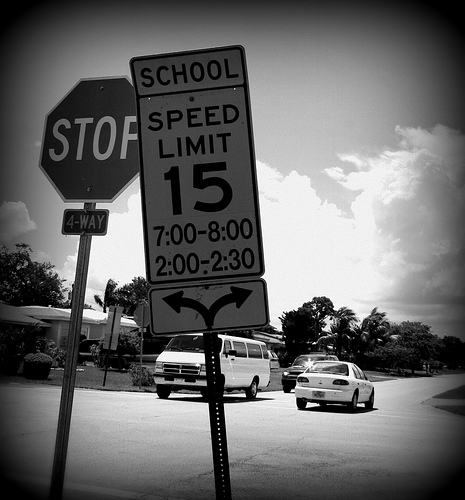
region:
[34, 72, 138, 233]
4-way stop sign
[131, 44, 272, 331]
school zone speed limit sign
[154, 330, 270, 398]
white van in intersectino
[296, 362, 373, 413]
white car in the intersection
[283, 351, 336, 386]
truck behind the white van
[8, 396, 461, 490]
intersection of two roads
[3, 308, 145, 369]
house on the corner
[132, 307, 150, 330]
stop sign on far corner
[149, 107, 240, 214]
speed limit in black lettering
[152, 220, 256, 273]
times under the 15 MPH speed limit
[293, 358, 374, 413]
A small white car.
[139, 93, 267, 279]
A speed limit sign.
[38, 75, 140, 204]
A stop sign.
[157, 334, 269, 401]
A large white van.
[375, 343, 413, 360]
part of a tree.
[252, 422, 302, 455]
Part of the road.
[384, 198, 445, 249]
Part of a cloud.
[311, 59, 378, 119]
Part of the sky.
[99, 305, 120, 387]
A sign on a pole.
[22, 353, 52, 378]
A small bush.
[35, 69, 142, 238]
there is a 4-way stop sign at this intersection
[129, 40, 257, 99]
there is a school close by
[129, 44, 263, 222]
there is a speed limit because a school is nearby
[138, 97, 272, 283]
the speed limit is for certain hours of the day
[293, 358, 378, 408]
a light colored sedan has just crossed the street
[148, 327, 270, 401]
a white van is about to enter the intersection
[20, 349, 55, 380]
a lovely manicured bush on the corner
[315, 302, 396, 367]
palm trees bent by the winds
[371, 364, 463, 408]
this street has no sidewalks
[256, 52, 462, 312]
it is a partly cloudy day today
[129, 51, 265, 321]
Signage in the photo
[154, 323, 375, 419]
Cars in the photo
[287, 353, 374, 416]
A white car in the photo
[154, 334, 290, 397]
A white van on the road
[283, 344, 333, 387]
A black car in the photo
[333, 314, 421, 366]
Trees in the photo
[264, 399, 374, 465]
Road in the tarmac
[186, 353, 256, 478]
A metal pole in the photo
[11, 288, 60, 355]
Houses in the photo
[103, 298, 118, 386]
A sign post in the photo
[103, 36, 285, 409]
a black and white speed sign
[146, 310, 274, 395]
a white van on road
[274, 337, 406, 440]
a white car on road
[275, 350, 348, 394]
a truck behind the van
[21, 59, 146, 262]
a stop sign on pole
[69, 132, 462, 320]
clouds in the sky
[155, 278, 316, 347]
black arrows on white sign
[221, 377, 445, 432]
white lines of crosswalk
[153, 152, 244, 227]
15 on the sign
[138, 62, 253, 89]
School in black letters